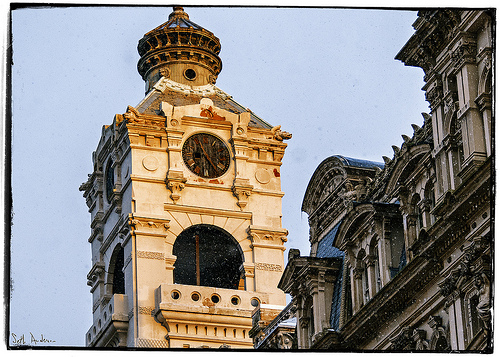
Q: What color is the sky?
A: Blue.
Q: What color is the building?
A: Yellow.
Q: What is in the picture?
A: Clock.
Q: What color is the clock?
A: Navy.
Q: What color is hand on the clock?
A: Red.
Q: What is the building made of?
A: Limestone.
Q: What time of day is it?
A: Morning.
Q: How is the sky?
A: Clear.